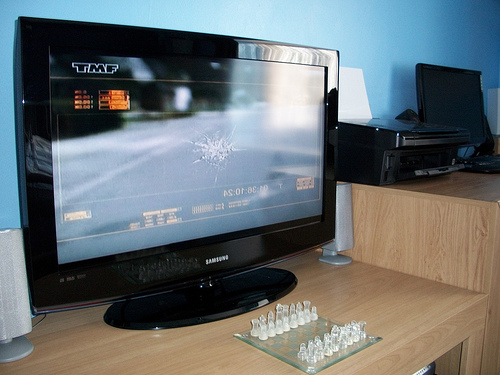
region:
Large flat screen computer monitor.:
[13, 15, 338, 300]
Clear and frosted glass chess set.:
[212, 290, 391, 370]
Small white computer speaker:
[2, 220, 40, 368]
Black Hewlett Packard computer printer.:
[336, 56, 476, 201]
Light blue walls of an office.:
[0, 1, 499, 233]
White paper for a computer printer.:
[336, 60, 373, 123]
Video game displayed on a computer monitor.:
[43, 30, 328, 271]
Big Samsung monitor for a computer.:
[7, 8, 342, 312]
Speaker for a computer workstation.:
[321, 181, 353, 266]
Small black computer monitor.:
[413, 60, 496, 155]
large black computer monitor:
[24, 18, 339, 323]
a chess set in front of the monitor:
[235, 302, 381, 374]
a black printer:
[340, 118, 472, 190]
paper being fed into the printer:
[338, 65, 375, 123]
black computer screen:
[415, 60, 487, 145]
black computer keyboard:
[470, 155, 499, 172]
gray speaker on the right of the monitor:
[325, 181, 353, 266]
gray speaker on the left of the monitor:
[0, 226, 35, 361]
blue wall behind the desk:
[0, 0, 496, 222]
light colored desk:
[5, 170, 497, 373]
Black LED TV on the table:
[13, 13, 342, 332]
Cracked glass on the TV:
[180, 121, 249, 181]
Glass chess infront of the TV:
[227, 295, 382, 372]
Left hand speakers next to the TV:
[0, 225, 40, 357]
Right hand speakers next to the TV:
[316, 180, 351, 261]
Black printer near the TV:
[335, 60, 476, 175]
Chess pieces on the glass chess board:
[248, 298, 318, 340]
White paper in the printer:
[334, 64, 374, 120]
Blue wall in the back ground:
[0, 0, 498, 230]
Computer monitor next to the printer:
[412, 61, 499, 171]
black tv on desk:
[17, 39, 369, 260]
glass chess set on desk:
[245, 285, 360, 366]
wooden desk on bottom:
[21, 210, 482, 373]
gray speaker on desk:
[1, 220, 33, 347]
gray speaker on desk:
[327, 176, 370, 258]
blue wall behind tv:
[65, 19, 393, 79]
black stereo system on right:
[334, 102, 499, 171]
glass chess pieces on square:
[295, 308, 352, 365]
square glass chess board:
[248, 302, 380, 370]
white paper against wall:
[307, 53, 391, 133]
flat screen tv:
[16, 17, 339, 329]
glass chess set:
[234, 300, 383, 370]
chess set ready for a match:
[232, 300, 382, 372]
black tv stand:
[99, 260, 298, 331]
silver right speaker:
[317, 182, 352, 265]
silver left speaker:
[1, 227, 35, 364]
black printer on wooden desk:
[328, 65, 464, 183]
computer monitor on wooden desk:
[415, 62, 485, 142]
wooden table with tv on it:
[2, 246, 487, 371]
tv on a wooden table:
[18, 18, 338, 330]